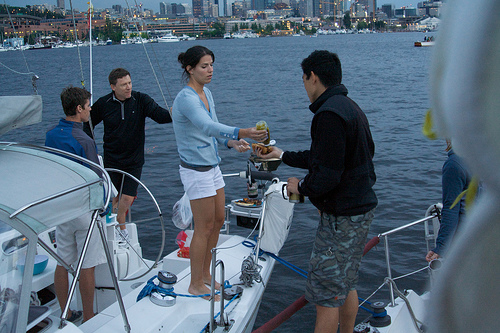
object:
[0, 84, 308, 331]
sailboat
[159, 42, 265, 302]
girl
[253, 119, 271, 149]
ketchup bottle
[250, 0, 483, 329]
sailboat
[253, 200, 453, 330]
safety rail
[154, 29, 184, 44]
yacht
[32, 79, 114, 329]
man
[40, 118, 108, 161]
jacket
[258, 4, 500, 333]
boat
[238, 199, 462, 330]
railing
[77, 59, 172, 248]
man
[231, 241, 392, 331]
rope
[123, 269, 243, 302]
rope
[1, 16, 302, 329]
boat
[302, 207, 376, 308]
shorts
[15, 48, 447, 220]
rivers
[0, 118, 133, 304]
shelter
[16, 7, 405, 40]
city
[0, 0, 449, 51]
background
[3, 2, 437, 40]
buildings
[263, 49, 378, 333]
guy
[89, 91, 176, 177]
black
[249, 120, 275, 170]
mustard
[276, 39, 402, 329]
man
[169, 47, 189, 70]
tail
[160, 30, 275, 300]
woman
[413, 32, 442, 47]
boat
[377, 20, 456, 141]
distance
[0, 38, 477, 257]
water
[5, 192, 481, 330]
harbor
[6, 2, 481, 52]
skyline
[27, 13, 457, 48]
harbor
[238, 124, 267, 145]
hand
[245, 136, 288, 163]
hotdog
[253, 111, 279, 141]
condiment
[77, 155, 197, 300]
wheel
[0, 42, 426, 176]
lake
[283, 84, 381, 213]
sweater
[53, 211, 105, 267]
shorts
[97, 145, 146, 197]
shorts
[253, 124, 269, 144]
ketchup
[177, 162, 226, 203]
shorts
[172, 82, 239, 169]
sweater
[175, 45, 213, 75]
hair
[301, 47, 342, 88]
hair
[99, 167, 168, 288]
steering wheel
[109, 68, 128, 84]
brown hair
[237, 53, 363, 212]
mans hotdog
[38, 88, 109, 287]
man wearing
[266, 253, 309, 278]
blue rope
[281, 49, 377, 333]
man holding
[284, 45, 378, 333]
man wearing